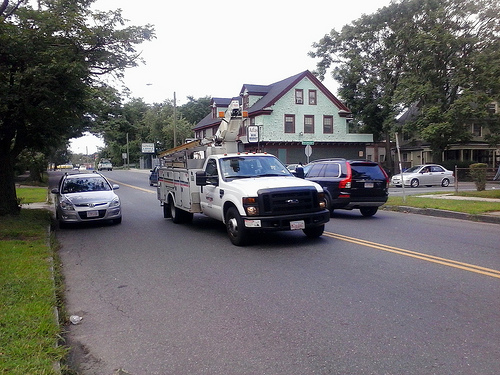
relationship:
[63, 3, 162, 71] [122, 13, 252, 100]
tree branches with sky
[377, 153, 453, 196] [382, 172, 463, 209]
car on side road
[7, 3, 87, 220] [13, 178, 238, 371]
tree along roadside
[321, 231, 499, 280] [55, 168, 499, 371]
line on street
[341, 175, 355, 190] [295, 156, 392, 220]
tail light on back of suv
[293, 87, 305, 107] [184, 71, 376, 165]
window on house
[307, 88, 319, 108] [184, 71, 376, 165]
window on house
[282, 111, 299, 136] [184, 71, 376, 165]
window on house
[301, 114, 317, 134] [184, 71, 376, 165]
window on house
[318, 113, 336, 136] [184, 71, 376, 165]
window on house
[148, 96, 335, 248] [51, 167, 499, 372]
truck driving on road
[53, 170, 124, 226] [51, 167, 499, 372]
car parked on side of road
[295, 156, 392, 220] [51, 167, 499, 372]
suv on road